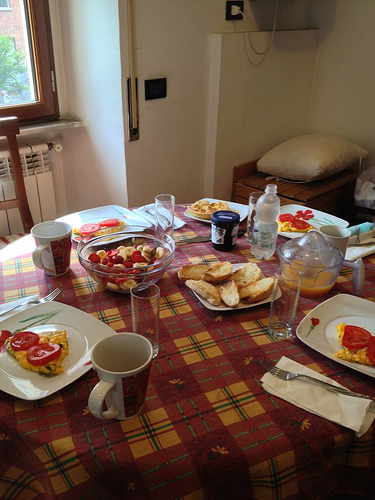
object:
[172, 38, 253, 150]
wall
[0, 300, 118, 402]
plate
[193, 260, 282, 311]
plate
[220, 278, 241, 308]
bread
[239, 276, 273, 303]
bread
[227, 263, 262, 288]
bread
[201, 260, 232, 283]
bread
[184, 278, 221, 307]
bread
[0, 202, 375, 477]
table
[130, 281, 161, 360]
glass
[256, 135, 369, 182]
tan pillow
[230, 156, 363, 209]
table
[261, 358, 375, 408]
fork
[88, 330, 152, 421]
mug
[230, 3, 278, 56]
white cord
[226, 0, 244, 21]
outlet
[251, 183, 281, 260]
bottle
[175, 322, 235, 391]
tablecloth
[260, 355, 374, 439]
napkin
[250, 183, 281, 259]
water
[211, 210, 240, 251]
dark glass